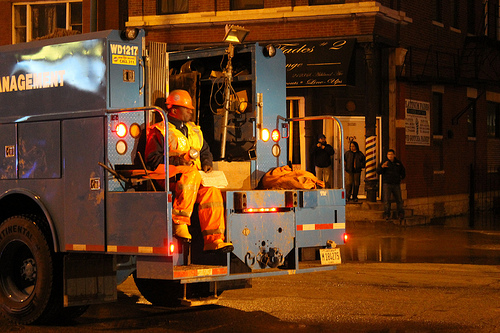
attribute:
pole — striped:
[361, 130, 378, 183]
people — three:
[313, 128, 408, 219]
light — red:
[114, 121, 128, 138]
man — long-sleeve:
[144, 84, 236, 255]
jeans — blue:
[342, 171, 363, 203]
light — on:
[269, 126, 282, 145]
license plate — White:
[316, 246, 341, 264]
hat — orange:
[164, 83, 204, 123]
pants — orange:
[144, 166, 225, 234]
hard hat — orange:
[167, 92, 194, 109]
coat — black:
[379, 157, 406, 171]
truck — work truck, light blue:
[0, 33, 350, 313]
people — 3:
[301, 129, 418, 235]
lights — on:
[260, 126, 281, 143]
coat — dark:
[321, 153, 373, 171]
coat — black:
[374, 159, 409, 183]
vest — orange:
[153, 118, 203, 165]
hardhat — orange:
[167, 89, 194, 111]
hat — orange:
[153, 87, 206, 113]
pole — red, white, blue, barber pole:
[360, 46, 382, 208]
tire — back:
[0, 208, 67, 323]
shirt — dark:
[142, 119, 216, 174]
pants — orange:
[182, 185, 269, 235]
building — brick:
[0, 1, 499, 224]